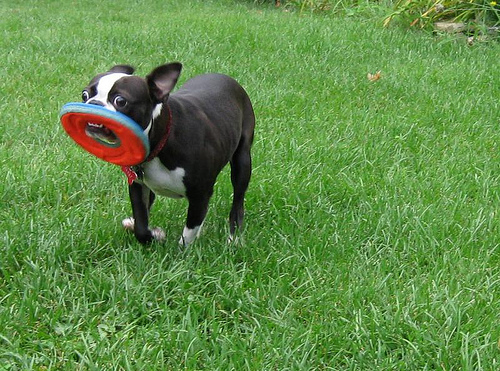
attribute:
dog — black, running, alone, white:
[100, 62, 262, 248]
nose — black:
[82, 95, 102, 118]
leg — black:
[167, 172, 207, 251]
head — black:
[78, 63, 177, 119]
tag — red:
[118, 166, 137, 182]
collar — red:
[155, 112, 176, 160]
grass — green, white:
[270, 36, 322, 73]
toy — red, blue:
[56, 105, 145, 172]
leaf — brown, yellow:
[360, 52, 384, 93]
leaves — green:
[376, 1, 437, 33]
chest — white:
[141, 165, 180, 188]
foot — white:
[174, 229, 208, 246]